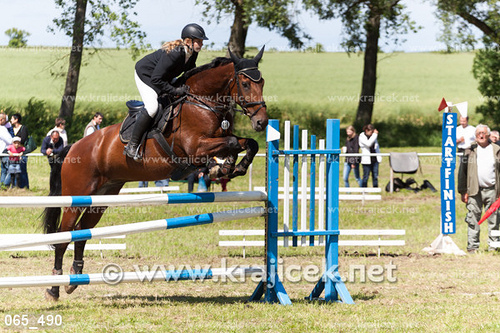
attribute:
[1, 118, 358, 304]
hurdle — blue, white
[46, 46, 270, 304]
horse — dark brown, brown, jumping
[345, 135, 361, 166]
coat — black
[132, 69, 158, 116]
riding pants — white, tight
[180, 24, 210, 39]
helmet — black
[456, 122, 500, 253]
man — elderly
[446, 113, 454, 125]
letter — white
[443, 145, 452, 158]
letter — white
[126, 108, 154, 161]
boots — black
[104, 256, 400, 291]
watermark — clear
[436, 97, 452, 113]
flag — small, red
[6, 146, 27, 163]
shirt — red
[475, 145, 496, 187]
shirt — white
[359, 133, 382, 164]
coat — white